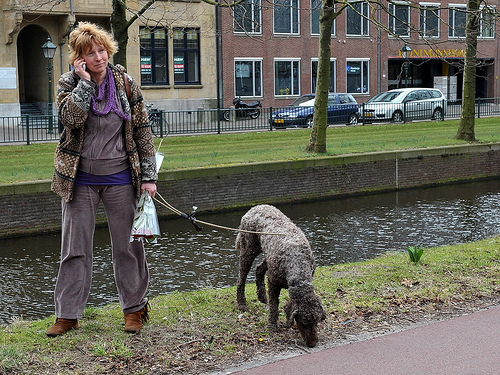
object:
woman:
[46, 20, 156, 334]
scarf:
[86, 66, 128, 125]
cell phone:
[76, 59, 86, 72]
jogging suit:
[45, 61, 160, 201]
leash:
[150, 191, 286, 236]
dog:
[234, 204, 327, 348]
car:
[269, 93, 361, 130]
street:
[0, 97, 499, 143]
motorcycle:
[222, 96, 261, 122]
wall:
[221, 2, 392, 121]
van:
[356, 87, 446, 126]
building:
[0, 0, 221, 132]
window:
[173, 29, 203, 83]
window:
[139, 28, 167, 83]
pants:
[50, 182, 149, 316]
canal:
[0, 176, 499, 326]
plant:
[406, 242, 424, 259]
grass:
[0, 118, 499, 185]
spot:
[0, 235, 499, 375]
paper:
[130, 151, 164, 244]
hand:
[140, 181, 156, 197]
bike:
[145, 103, 170, 138]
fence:
[1, 96, 500, 145]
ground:
[3, 235, 499, 372]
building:
[219, 1, 500, 117]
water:
[1, 177, 499, 326]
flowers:
[128, 139, 166, 244]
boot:
[46, 316, 80, 338]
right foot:
[46, 318, 79, 338]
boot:
[123, 301, 152, 333]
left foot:
[122, 296, 151, 332]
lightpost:
[40, 37, 58, 134]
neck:
[88, 70, 108, 84]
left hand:
[73, 57, 91, 81]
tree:
[242, 0, 426, 153]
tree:
[415, 0, 500, 141]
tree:
[1, 0, 246, 74]